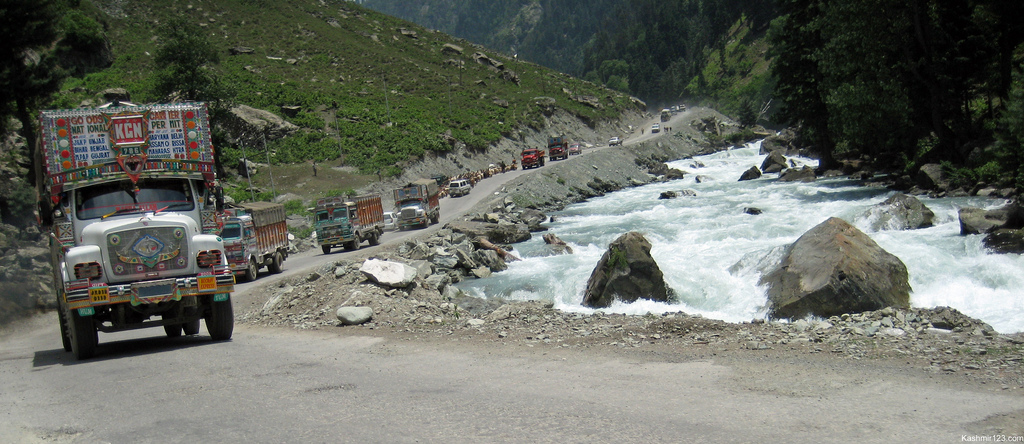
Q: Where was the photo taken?
A: On a mountain road.